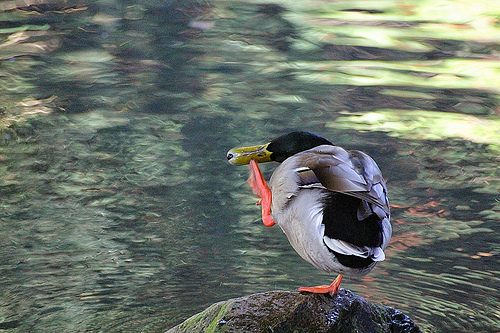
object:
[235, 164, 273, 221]
feet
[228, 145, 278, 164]
beak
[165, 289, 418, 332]
rock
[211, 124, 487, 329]
duck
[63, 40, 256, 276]
water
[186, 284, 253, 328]
part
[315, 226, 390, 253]
wing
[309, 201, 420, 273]
tail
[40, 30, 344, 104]
body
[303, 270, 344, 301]
leg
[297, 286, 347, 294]
part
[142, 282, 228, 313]
waves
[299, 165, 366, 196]
feather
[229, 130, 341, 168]
head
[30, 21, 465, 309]
photo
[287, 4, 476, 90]
day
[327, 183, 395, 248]
feathers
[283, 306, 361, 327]
surface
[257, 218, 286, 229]
knee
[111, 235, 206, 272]
part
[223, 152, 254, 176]
tip